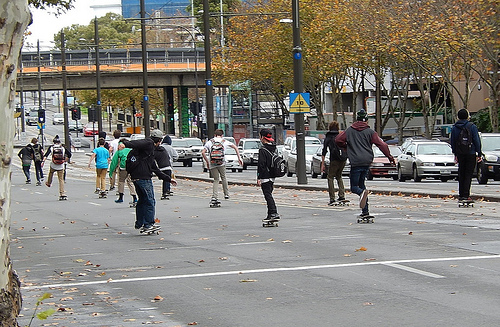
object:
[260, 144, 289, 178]
backpack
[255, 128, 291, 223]
man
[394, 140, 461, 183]
cars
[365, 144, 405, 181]
cars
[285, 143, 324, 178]
cars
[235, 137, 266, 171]
cars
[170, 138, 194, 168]
cars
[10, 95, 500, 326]
street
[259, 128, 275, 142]
cap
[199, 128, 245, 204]
person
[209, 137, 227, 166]
backpack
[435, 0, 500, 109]
tree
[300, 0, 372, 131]
tree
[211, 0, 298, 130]
tree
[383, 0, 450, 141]
tree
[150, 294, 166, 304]
leafs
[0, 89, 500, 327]
ground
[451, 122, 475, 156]
backpack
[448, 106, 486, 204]
skateboarder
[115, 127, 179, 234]
skateboarder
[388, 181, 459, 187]
divider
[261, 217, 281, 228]
skateboard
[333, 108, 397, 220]
person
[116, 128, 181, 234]
person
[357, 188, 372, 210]
foot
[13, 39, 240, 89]
overpass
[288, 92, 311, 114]
sign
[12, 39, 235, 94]
bridge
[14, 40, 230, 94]
bridge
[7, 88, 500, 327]
roadway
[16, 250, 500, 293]
lanes